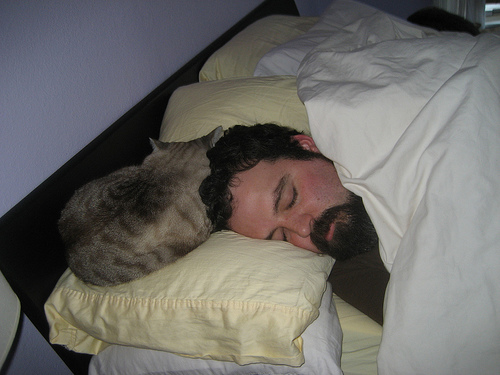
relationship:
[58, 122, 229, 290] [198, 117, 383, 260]
cat near head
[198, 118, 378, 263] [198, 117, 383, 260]
head has head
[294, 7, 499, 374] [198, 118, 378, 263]
sheet over head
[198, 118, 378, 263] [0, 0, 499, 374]
head in bed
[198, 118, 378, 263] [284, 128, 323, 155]
head has ear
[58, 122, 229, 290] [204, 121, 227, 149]
cat has ear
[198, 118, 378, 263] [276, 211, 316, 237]
head has nose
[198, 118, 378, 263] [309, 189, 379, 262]
head has beard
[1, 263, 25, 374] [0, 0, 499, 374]
lampshade next to bed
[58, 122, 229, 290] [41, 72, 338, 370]
cat on pillow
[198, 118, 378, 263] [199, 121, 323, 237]
head has hair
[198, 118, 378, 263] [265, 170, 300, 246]
head has eyes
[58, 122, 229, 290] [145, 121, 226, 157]
cat has ears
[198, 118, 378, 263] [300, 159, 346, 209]
head has cheek